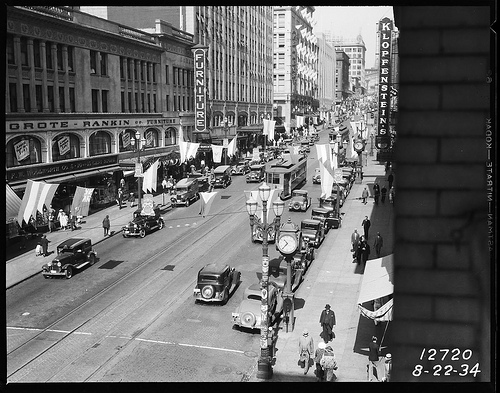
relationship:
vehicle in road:
[193, 249, 238, 315] [90, 122, 309, 326]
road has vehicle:
[90, 122, 309, 326] [193, 249, 238, 315]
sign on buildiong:
[15, 112, 163, 131] [37, 0, 207, 173]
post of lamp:
[248, 197, 278, 378] [245, 180, 308, 222]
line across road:
[46, 318, 285, 392] [5, 113, 370, 385]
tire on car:
[61, 263, 77, 289] [40, 237, 106, 294]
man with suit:
[318, 298, 343, 330] [320, 320, 334, 346]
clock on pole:
[264, 217, 316, 254] [280, 256, 304, 318]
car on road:
[40, 237, 106, 294] [5, 113, 370, 385]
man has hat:
[318, 298, 343, 330] [325, 303, 335, 314]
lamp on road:
[245, 180, 308, 222] [5, 113, 370, 385]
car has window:
[40, 237, 106, 294] [83, 244, 92, 253]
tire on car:
[61, 263, 74, 280] [40, 237, 106, 294]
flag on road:
[72, 185, 106, 232] [5, 113, 370, 385]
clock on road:
[264, 217, 316, 254] [5, 113, 370, 385]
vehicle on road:
[193, 249, 238, 315] [22, 73, 322, 376]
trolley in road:
[255, 140, 304, 214] [5, 113, 370, 385]